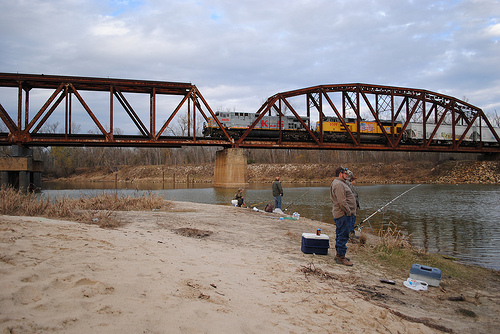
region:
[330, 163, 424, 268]
Men fishing near side of water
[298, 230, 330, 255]
Cooler on the ground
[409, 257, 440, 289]
Tackle box on the ground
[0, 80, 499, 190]
Bridge crossing the river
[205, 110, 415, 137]
Train on the bridge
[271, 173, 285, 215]
Man standing on the shore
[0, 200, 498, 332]
Sand and dirt along the shoreline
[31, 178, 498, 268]
Calm body of water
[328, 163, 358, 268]
Man standing on the shore.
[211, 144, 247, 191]
Cement support under the bridge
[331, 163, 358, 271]
man standing on the side of a lake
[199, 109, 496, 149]
train going over a bridge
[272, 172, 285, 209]
man looking up at the train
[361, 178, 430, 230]
fishing pole on the side of a lake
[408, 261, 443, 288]
blue and white tackle box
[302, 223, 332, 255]
dark blue and white ice chest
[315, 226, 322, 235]
can on top of the ice chest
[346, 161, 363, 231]
people fishing in the lake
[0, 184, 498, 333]
sandy area next to the lake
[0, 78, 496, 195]
bridge going over a river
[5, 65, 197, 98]
rusty iron bridge beam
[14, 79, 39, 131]
rusty iron bridge beam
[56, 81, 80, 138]
rusty iron bridge beam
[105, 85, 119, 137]
rusty iron bridge beam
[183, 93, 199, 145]
rusty iron bridge beam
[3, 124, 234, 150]
rusty iron bridge beam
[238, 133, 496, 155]
rusty iron bridge beam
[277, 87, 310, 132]
rusty iron bridge beam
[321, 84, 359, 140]
rusty iron bridge beam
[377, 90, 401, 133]
rusty iron bridge beam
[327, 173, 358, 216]
the arm of a man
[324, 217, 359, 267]
the leg of a man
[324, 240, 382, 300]
the feet of a man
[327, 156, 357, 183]
the ear of a man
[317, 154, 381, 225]
a man wearing a hat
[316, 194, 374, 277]
a man wearing pants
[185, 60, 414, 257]
a man near a train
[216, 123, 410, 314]
a man near a lake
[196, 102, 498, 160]
train on the bridge tracks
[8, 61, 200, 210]
bridge over top of the water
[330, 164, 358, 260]
man looking at the horizion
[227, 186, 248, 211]
person sitting on cooler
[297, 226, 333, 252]
can of drink on top of cooler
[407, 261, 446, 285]
fishing tackle box with blue lid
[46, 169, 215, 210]
calm waters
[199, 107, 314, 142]
the train engine is gray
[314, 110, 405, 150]
train engine is yellow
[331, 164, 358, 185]
the head of a man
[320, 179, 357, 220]
the shirt of a man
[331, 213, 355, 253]
the pants of a man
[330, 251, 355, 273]
the shoes of a man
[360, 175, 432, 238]
the fishing pole of a man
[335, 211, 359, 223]
the pocket of a man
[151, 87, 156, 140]
bridge has a rail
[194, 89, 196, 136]
bridge has a rail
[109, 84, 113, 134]
bridge has a rail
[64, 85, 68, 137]
bridge has a rail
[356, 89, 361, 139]
bridge has a rail